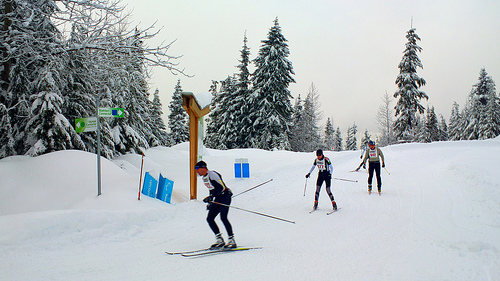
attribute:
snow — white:
[0, 141, 499, 279]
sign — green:
[98, 106, 126, 118]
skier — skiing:
[194, 159, 238, 247]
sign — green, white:
[75, 116, 100, 132]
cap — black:
[194, 160, 208, 169]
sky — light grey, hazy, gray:
[50, 0, 499, 141]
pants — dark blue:
[205, 194, 235, 240]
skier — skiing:
[311, 157, 338, 210]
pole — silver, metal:
[95, 96, 102, 195]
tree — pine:
[252, 16, 293, 151]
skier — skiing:
[363, 141, 386, 192]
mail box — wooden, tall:
[183, 89, 214, 199]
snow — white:
[0, 145, 175, 210]